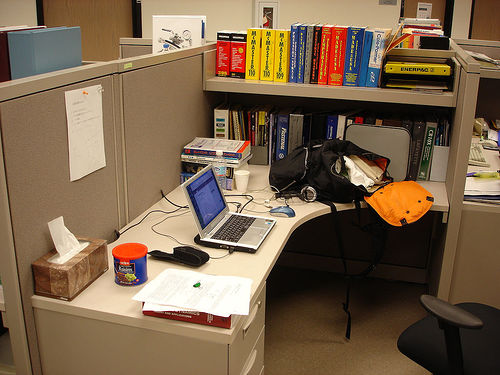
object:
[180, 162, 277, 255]
laptop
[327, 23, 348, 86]
book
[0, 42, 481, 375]
cubicle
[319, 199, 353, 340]
strap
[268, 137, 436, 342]
back pack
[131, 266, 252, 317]
paper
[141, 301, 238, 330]
book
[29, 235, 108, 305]
box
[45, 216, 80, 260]
tissue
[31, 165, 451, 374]
desk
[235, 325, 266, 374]
drawers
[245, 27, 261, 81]
books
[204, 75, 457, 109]
shelf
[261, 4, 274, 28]
picture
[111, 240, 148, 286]
can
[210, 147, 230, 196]
bottle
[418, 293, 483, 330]
arm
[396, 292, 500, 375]
chair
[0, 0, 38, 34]
wall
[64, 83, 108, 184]
paper